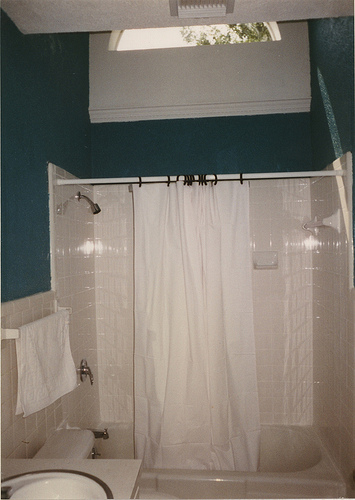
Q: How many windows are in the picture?
A: One.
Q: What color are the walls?
A: Blue.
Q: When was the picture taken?
A: During the day.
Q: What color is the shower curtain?
A: White.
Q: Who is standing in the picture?
A: No one.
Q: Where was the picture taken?
A: In the bathroom.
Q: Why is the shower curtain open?
A: No one is using it.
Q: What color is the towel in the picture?
A: White.